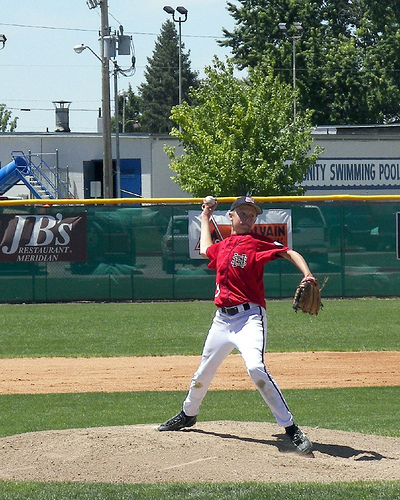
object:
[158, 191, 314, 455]
boy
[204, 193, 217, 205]
baseball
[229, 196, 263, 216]
cap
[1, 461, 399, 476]
dirt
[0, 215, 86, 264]
sign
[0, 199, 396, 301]
fence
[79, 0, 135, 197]
power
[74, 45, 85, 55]
light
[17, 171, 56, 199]
stairs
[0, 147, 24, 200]
waterslide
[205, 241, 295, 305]
uniform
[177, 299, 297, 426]
pants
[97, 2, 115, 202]
brown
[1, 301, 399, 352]
field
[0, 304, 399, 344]
grass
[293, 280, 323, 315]
hand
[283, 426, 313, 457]
cleat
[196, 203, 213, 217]
hand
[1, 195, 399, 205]
pad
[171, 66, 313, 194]
small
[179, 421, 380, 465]
shadow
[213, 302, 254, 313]
belt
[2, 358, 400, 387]
soil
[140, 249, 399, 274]
road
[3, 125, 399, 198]
building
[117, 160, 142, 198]
door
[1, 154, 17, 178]
blue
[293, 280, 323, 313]
glove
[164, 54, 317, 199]
tree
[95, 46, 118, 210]
pole